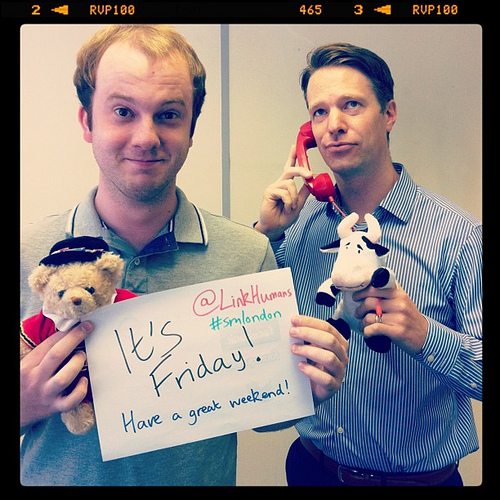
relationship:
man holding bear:
[16, 24, 350, 489] [20, 236, 138, 436]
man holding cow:
[252, 44, 484, 490] [316, 211, 396, 351]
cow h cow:
[316, 211, 396, 351] [313, 206, 400, 358]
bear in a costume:
[20, 236, 138, 436] [20, 236, 141, 437]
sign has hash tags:
[82, 266, 316, 463] [207, 309, 283, 332]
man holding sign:
[16, 24, 350, 489] [82, 266, 316, 463]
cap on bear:
[38, 236, 110, 259] [20, 236, 138, 436]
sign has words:
[82, 266, 316, 463] [113, 286, 293, 434]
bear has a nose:
[20, 236, 138, 436] [70, 298, 82, 307]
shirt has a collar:
[254, 162, 483, 474] [326, 163, 419, 225]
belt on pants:
[298, 434, 456, 483] [286, 433, 465, 486]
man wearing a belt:
[252, 44, 484, 490] [298, 434, 456, 483]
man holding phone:
[252, 44, 484, 490] [297, 120, 384, 323]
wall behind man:
[20, 24, 482, 488] [16, 24, 350, 489]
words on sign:
[113, 286, 293, 434] [82, 266, 316, 463]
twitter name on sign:
[193, 285, 294, 317] [82, 266, 316, 463]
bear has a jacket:
[20, 236, 138, 436] [21, 289, 139, 402]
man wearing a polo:
[16, 24, 350, 489] [20, 185, 280, 487]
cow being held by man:
[316, 211, 396, 351] [252, 44, 484, 490]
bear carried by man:
[20, 236, 138, 436] [16, 24, 350, 489]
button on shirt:
[426, 354, 435, 364] [254, 162, 483, 474]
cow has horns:
[316, 211, 396, 351] [337, 213, 382, 243]